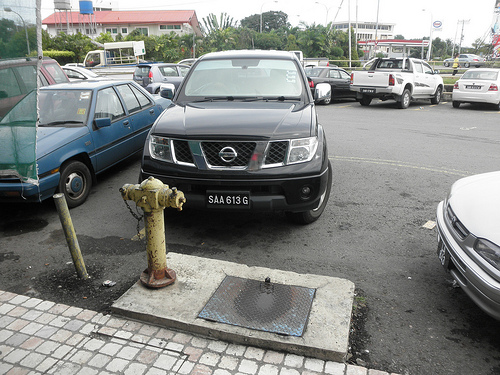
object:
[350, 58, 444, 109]
truck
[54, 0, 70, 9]
water tank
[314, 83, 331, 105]
rearview mirror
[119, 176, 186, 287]
fire hydrant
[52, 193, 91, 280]
metal rod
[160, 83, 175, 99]
sideview mirror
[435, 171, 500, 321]
car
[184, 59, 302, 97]
windshield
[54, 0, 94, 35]
water towers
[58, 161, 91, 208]
black wheel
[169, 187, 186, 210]
cap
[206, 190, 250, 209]
license plate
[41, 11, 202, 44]
building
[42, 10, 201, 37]
roof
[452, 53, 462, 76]
person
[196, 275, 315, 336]
drain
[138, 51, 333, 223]
black suv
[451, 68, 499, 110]
sedan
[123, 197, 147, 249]
chain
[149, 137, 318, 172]
grill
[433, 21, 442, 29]
sign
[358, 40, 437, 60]
gas station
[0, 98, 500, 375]
ground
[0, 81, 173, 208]
vehicle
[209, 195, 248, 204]
lettering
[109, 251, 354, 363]
slab